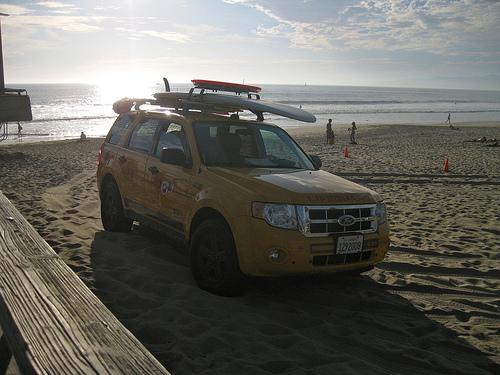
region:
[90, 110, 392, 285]
a yellow SUV on the beach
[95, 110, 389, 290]
a yellow Ford SUV on the beach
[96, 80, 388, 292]
a yellow vehicle on the beach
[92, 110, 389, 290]
a yellow 4 door on the beach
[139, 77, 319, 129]
surfboard on the roof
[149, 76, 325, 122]
surfboard on a rack on the roof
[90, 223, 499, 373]
shadow of a vehicle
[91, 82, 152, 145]
reflection of the sun on the water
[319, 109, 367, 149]
people on the beach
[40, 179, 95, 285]
footprints on the sand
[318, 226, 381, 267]
State license tag on front of yellow vehicle.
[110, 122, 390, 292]
Ford vehicle with the word, lifeguard, on the front.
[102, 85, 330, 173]
Surfboard on top of a yellow SUV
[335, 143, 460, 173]
Orange traffic cones in the sand.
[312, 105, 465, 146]
People standing and walking on the beach.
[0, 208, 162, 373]
Weathered wooden railing.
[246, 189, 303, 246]
Headlight.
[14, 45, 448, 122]
Sun setting behind the ocean.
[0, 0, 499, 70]
Blue sky with white clouds.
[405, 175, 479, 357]
Sandy beach.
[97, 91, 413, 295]
a yellow lifeguard car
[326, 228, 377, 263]
a white license plate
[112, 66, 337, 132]
a surfboard on the car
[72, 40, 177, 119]
the sun reflecting off the water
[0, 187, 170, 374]
a piece of wood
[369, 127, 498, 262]
sand with many footprints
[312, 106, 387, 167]
people playing a game on the beach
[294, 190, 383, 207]
red words that say LIFEGUARD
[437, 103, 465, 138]
a person running on the beach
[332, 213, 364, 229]
the Ford emblem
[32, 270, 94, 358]
jagged line on washed out wood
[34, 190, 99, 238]
footprints in the sand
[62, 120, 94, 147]
person sitting on sand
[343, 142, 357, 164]
orange cone on sand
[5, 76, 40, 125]
edge of cliff in the water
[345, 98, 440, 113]
small waves breaking towards the shore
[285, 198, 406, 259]
silver grill on the yellow truck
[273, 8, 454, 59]
white clouds in the sky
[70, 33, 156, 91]
light reflecting on the water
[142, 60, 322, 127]
gray surfboard on top of the truck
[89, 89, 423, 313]
yellow emergency vehicle on beach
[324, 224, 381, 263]
license tag on front of vehicle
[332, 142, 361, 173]
reflective orange safety cone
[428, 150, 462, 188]
reflective orange safety cone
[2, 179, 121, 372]
wooden plant railing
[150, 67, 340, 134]
surfboards attached to an emergency vehicle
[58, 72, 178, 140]
sun reflecting off body of water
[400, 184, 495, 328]
light brown dry beach sand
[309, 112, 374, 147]
tow people walking on the beach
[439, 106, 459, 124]
person running on beach at a distance